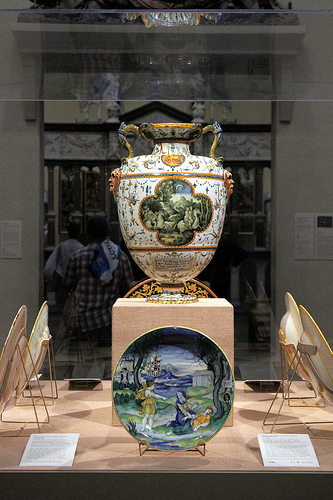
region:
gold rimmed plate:
[99, 326, 238, 453]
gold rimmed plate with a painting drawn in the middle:
[110, 327, 238, 448]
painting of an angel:
[135, 370, 166, 439]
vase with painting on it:
[104, 115, 239, 291]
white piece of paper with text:
[28, 429, 77, 474]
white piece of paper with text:
[261, 429, 319, 470]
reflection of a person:
[62, 215, 121, 336]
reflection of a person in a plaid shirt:
[68, 228, 122, 335]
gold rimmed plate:
[299, 306, 331, 399]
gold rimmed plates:
[0, 295, 58, 413]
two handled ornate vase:
[98, 111, 247, 310]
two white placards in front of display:
[18, 424, 326, 472]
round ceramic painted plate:
[103, 319, 241, 453]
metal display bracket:
[1, 344, 53, 440]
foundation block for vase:
[107, 288, 246, 437]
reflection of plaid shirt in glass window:
[61, 238, 137, 339]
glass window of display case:
[2, 4, 324, 474]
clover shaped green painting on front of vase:
[130, 177, 218, 251]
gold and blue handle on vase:
[200, 121, 228, 163]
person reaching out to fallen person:
[132, 376, 216, 435]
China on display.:
[250, 282, 331, 419]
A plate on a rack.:
[92, 334, 226, 454]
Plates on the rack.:
[2, 301, 65, 434]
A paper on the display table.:
[246, 419, 327, 484]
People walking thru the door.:
[53, 223, 136, 339]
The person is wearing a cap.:
[80, 208, 116, 235]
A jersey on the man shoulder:
[96, 240, 118, 284]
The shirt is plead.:
[62, 257, 122, 323]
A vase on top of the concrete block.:
[108, 130, 232, 297]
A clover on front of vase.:
[143, 180, 217, 251]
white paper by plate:
[19, 430, 81, 467]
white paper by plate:
[256, 430, 315, 465]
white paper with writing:
[258, 432, 316, 466]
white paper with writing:
[25, 432, 75, 466]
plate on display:
[117, 325, 234, 447]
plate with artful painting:
[112, 326, 233, 449]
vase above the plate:
[110, 122, 234, 302]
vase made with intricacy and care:
[105, 122, 232, 300]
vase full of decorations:
[101, 121, 233, 299]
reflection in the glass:
[49, 222, 134, 371]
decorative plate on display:
[114, 316, 245, 462]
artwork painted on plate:
[108, 327, 246, 457]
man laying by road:
[174, 405, 223, 435]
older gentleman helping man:
[171, 389, 198, 437]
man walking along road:
[137, 369, 168, 439]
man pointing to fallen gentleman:
[128, 380, 170, 437]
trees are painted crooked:
[205, 354, 226, 423]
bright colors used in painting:
[124, 328, 233, 458]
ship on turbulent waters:
[148, 356, 181, 387]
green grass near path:
[189, 386, 210, 410]